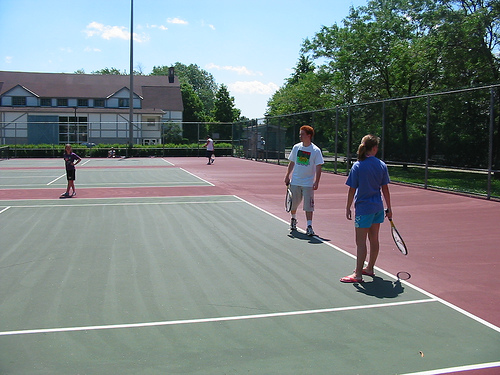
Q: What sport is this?
A: Tennis.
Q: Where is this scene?
A: Tennis court.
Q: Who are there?
A: People.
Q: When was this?
A: Daytime.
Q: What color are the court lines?
A: White.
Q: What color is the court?
A: Green.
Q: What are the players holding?
A: Raquet.